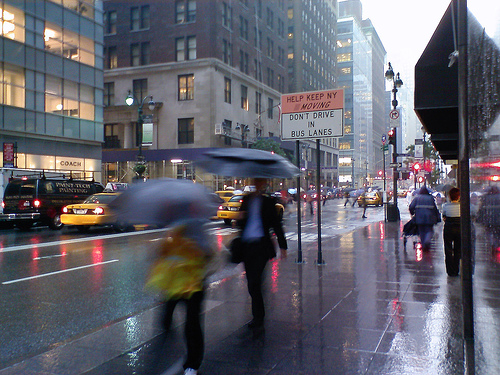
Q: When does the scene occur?
A: Daytime.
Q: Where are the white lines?
A: On the street.